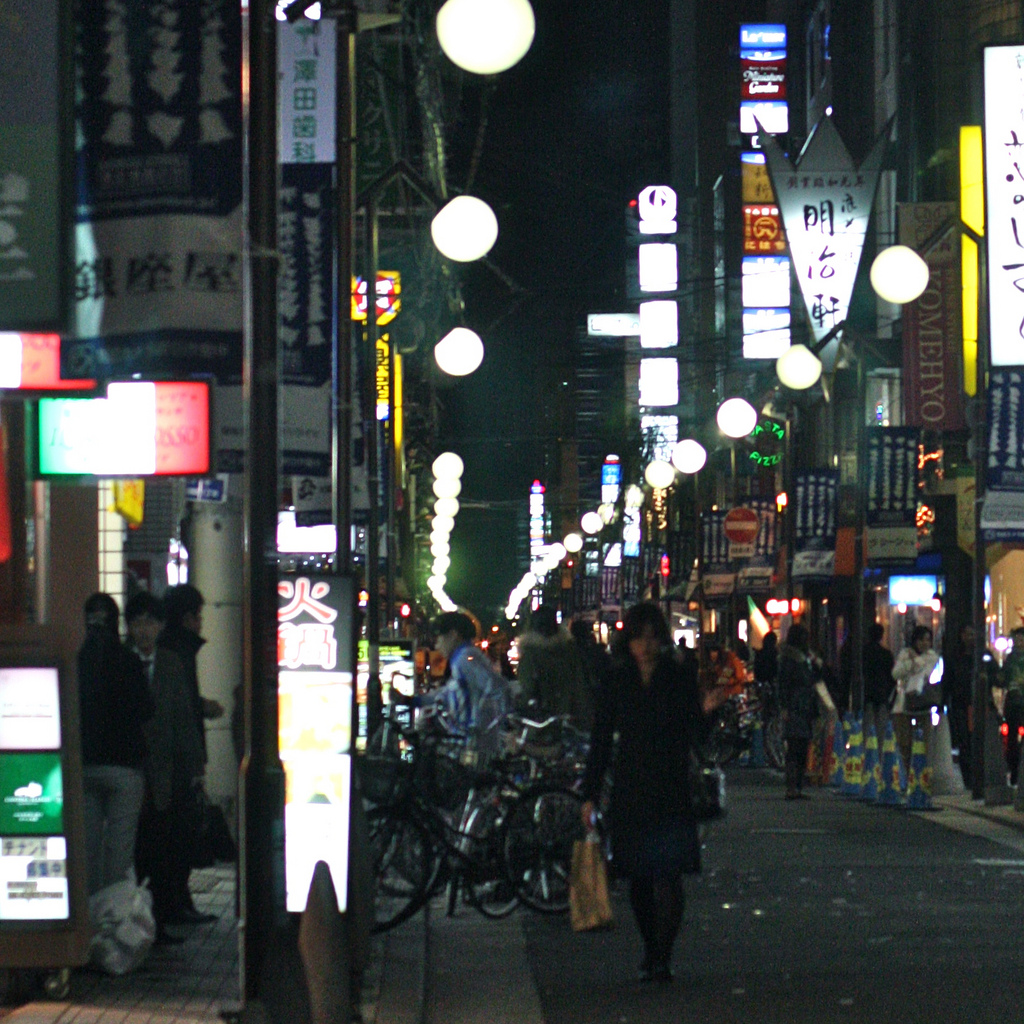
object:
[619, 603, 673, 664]
head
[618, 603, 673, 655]
hair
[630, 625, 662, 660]
face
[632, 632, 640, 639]
eyes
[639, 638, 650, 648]
nose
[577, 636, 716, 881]
jacket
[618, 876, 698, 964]
legs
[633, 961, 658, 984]
shoes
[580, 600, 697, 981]
women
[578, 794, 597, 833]
hand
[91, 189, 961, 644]
outdoors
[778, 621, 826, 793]
people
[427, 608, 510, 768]
man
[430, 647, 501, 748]
shirt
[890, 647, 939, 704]
shirt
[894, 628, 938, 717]
person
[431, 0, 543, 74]
light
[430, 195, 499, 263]
light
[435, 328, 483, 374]
light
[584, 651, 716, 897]
clothes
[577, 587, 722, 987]
woman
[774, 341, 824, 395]
light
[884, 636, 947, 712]
top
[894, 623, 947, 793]
girl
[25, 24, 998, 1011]
view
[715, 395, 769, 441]
streetlight